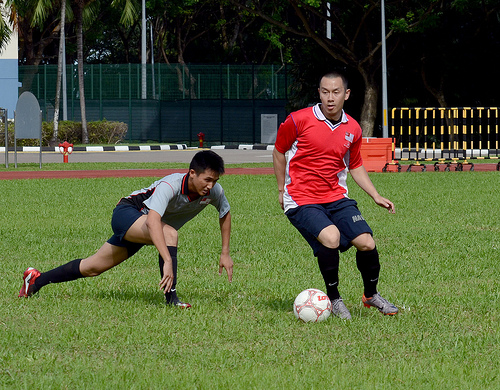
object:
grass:
[417, 200, 500, 253]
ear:
[345, 89, 350, 100]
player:
[16, 149, 234, 308]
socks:
[356, 245, 381, 299]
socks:
[317, 246, 340, 300]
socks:
[158, 246, 182, 304]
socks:
[33, 259, 86, 295]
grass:
[0, 163, 273, 172]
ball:
[293, 288, 332, 323]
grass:
[1, 172, 85, 244]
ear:
[189, 169, 195, 178]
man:
[18, 150, 234, 309]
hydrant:
[58, 141, 73, 163]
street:
[88, 150, 190, 162]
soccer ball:
[292, 288, 332, 323]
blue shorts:
[283, 198, 373, 258]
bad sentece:
[168, 329, 192, 343]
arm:
[215, 196, 233, 283]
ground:
[0, 147, 500, 390]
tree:
[0, 0, 74, 143]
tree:
[76, 0, 138, 144]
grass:
[75, 142, 170, 146]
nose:
[207, 185, 213, 189]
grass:
[102, 317, 262, 390]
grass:
[32, 303, 164, 379]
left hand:
[373, 197, 395, 214]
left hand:
[219, 254, 234, 283]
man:
[272, 71, 400, 320]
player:
[271, 72, 398, 320]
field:
[0, 165, 500, 390]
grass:
[407, 171, 500, 232]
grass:
[207, 315, 227, 335]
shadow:
[34, 289, 163, 302]